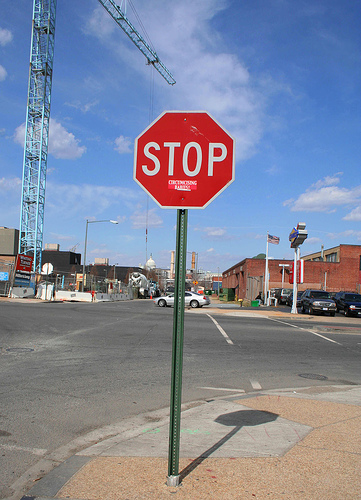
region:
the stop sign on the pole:
[132, 93, 243, 221]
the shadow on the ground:
[176, 408, 278, 496]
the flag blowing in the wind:
[260, 226, 282, 290]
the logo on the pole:
[281, 219, 308, 254]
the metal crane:
[7, 8, 174, 274]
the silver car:
[155, 290, 214, 311]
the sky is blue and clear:
[220, 5, 355, 170]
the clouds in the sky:
[135, 1, 246, 122]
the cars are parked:
[301, 284, 358, 318]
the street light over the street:
[78, 208, 128, 293]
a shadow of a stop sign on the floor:
[184, 395, 287, 473]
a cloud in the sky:
[287, 173, 359, 221]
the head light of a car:
[310, 298, 320, 309]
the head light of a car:
[328, 300, 337, 308]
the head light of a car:
[348, 302, 357, 310]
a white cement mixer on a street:
[127, 269, 155, 299]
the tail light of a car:
[201, 294, 208, 301]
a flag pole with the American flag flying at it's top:
[263, 232, 280, 302]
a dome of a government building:
[143, 251, 160, 267]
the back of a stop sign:
[40, 260, 54, 301]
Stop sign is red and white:
[130, 107, 235, 209]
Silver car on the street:
[151, 291, 208, 308]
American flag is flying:
[263, 232, 280, 245]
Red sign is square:
[12, 251, 37, 274]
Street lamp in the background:
[79, 217, 118, 265]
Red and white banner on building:
[285, 257, 307, 285]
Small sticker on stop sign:
[168, 177, 198, 190]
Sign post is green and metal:
[167, 210, 187, 476]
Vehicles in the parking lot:
[273, 287, 358, 315]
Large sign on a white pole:
[286, 223, 308, 313]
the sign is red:
[93, 84, 262, 235]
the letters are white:
[125, 119, 241, 199]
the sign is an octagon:
[102, 88, 252, 230]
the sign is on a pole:
[163, 199, 203, 437]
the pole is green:
[154, 195, 214, 444]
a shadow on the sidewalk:
[186, 386, 284, 484]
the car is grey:
[145, 285, 220, 321]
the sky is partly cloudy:
[13, 38, 328, 240]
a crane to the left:
[7, 1, 169, 261]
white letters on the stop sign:
[140, 143, 223, 175]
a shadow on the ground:
[216, 396, 282, 432]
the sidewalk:
[273, 399, 346, 493]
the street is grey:
[67, 307, 157, 417]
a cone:
[148, 289, 153, 299]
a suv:
[305, 283, 335, 314]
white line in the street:
[209, 322, 228, 337]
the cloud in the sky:
[283, 187, 350, 210]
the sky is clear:
[240, 183, 271, 213]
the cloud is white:
[287, 187, 347, 215]